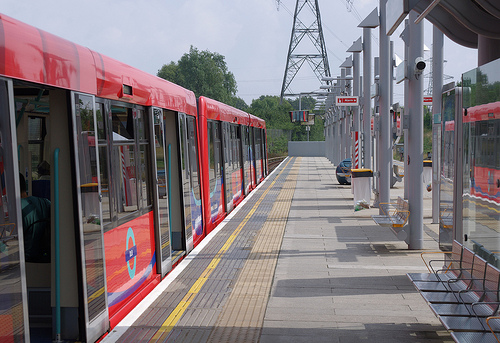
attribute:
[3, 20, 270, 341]
commutertrain — shiny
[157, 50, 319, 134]
trees — green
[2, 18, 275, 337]
train — red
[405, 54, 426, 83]
camera — small, white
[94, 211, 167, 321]
logo — blue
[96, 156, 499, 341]
platform — gray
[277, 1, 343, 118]
power scaffolding — large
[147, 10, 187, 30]
sky — blue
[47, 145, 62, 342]
pole — green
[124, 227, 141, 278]
logo — turquoise, navy, circular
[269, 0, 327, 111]
pole — tall, gray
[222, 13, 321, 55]
clouds — white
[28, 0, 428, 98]
sky — blue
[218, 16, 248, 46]
clouds — white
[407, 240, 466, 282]
seat — metal, red, silver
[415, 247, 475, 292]
seat — metal, red, silver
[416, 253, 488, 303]
seat — metal, red, silver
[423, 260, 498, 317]
seat — metal, red, silver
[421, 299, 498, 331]
seat — metal, red, silver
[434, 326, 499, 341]
seat — metal, red, silver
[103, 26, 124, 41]
clouds — white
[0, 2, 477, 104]
sky — blue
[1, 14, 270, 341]
train cars — red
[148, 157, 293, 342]
line — yellow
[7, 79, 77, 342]
door — open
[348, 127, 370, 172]
traffic pole — red, white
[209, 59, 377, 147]
trees — green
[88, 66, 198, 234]
train — red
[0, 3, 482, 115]
sky — blue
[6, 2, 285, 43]
sky — grey, overcast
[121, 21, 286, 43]
clouds — white